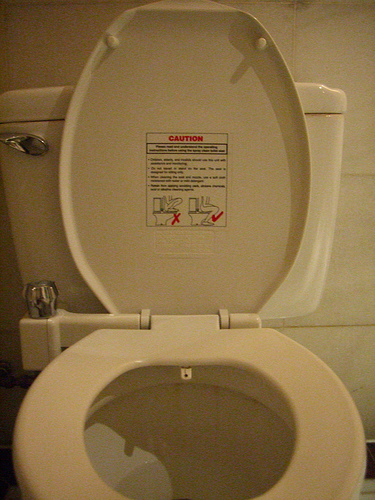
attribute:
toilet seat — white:
[7, 312, 369, 499]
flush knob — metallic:
[0, 123, 53, 159]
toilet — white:
[2, 3, 368, 498]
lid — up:
[54, 11, 315, 320]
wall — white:
[9, 16, 352, 374]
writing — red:
[166, 130, 204, 141]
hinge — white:
[134, 307, 158, 332]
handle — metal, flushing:
[5, 126, 50, 160]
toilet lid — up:
[53, 9, 325, 315]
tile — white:
[293, 8, 357, 172]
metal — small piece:
[177, 368, 189, 380]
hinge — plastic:
[137, 305, 152, 328]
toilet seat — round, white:
[9, 316, 359, 487]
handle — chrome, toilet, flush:
[5, 130, 49, 159]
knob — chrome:
[19, 278, 68, 314]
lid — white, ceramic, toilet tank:
[7, 79, 347, 126]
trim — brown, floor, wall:
[362, 443, 363, 468]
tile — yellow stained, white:
[291, 3, 360, 176]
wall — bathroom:
[19, 19, 359, 411]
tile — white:
[338, 227, 365, 286]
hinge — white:
[209, 304, 251, 339]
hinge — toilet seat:
[209, 306, 253, 335]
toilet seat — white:
[72, 336, 337, 497]